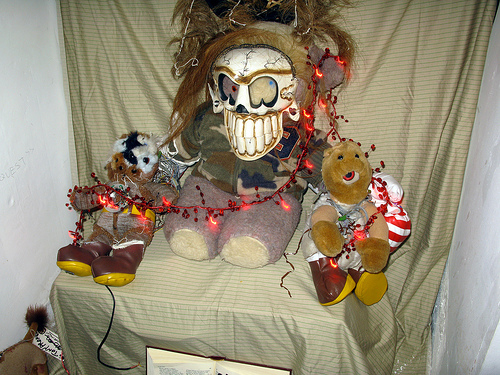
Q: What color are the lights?
A: Red.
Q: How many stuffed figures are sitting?
A: Three.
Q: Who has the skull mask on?
A: The middle one.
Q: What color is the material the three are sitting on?
A: White.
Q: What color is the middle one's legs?
A: Purple.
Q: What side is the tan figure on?
A: Left.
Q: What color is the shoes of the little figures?
A: Purple and yellow.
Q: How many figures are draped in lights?
A: Three.